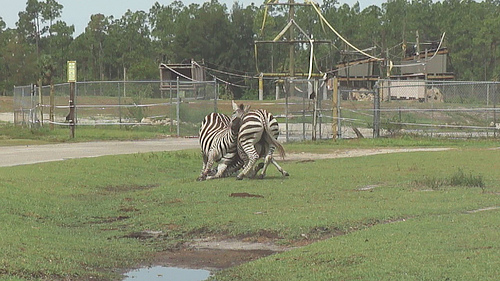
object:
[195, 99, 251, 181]
zebra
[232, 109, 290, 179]
zebra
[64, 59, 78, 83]
sign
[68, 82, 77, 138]
post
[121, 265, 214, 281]
water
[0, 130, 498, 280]
grass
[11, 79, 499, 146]
fence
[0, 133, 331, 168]
road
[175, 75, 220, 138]
gate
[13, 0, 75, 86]
trees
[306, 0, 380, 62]
cable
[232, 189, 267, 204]
dirt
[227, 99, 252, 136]
head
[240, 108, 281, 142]
rear end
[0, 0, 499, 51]
sky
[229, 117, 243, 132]
snout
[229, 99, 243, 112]
ear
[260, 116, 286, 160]
tail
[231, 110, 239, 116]
eye